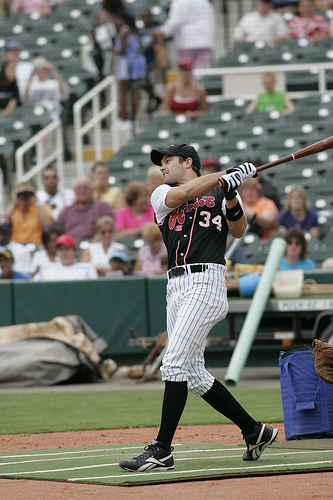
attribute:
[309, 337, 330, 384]
baseball glove — leather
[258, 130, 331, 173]
bat — baseball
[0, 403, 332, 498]
dirt — red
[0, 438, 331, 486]
mat — green, white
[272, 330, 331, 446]
fabric bin — blue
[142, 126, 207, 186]
hat — black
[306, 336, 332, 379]
glove — brown 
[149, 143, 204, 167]
cap — black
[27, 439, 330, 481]
mat — green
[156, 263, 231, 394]
uniform pants — baseball, white, black-striped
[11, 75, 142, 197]
railing — hand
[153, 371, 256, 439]
socks — knee high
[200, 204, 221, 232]
number — 34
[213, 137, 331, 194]
bat — dark brown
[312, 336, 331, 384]
mitt — brown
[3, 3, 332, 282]
spectators — group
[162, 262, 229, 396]
pants — striped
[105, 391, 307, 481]
cleat — blakc, white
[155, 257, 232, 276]
belt — black, leather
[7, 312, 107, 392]
tarp — grey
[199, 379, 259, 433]
stocking — Black , knee-high 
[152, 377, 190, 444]
stocking — knee-high , Black 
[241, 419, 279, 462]
sneaker — black and white 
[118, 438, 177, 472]
sneaker — black and white 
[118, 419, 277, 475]
cleats — black, white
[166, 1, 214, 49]
jacket — white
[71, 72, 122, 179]
rail — White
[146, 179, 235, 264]
jersey — black, white, red, baseball jersey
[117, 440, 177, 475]
shoe — black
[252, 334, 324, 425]
bag — blue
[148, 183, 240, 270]
jersey — black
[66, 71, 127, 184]
railing — white 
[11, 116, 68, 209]
railing — white 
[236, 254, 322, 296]
shirt — blue 